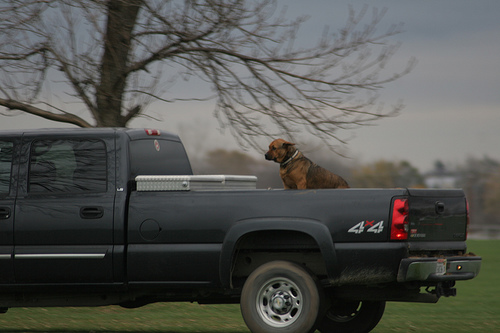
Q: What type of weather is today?
A: It is cloudy.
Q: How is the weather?
A: It is cloudy.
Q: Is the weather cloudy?
A: Yes, it is cloudy.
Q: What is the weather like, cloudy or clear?
A: It is cloudy.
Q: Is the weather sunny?
A: No, it is cloudy.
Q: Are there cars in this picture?
A: No, there are no cars.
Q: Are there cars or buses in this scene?
A: No, there are no cars or buses.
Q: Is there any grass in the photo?
A: Yes, there is grass.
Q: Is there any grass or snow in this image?
A: Yes, there is grass.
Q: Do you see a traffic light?
A: No, there are no traffic lights.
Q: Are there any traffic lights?
A: No, there are no traffic lights.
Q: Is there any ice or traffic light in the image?
A: No, there are no traffic lights or ice.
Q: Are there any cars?
A: No, there are no cars.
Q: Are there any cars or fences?
A: No, there are no cars or fences.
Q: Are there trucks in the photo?
A: Yes, there is a truck.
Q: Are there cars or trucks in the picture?
A: Yes, there is a truck.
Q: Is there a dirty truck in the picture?
A: Yes, there is a dirty truck.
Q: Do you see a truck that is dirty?
A: Yes, there is a truck that is dirty.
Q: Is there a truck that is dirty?
A: Yes, there is a truck that is dirty.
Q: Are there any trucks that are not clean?
A: Yes, there is a dirty truck.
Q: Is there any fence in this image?
A: No, there are no fences.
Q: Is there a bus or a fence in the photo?
A: No, there are no fences or buses.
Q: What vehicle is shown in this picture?
A: The vehicle is a truck.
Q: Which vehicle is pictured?
A: The vehicle is a truck.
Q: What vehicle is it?
A: The vehicle is a truck.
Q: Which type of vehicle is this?
A: That is a truck.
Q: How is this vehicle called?
A: That is a truck.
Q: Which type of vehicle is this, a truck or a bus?
A: That is a truck.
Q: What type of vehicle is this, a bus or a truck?
A: That is a truck.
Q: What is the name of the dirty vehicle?
A: The vehicle is a truck.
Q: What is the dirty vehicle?
A: The vehicle is a truck.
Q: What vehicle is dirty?
A: The vehicle is a truck.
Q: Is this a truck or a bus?
A: This is a truck.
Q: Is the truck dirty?
A: Yes, the truck is dirty.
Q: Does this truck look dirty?
A: Yes, the truck is dirty.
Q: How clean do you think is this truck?
A: The truck is dirty.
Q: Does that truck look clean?
A: No, the truck is dirty.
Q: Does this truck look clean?
A: No, the truck is dirty.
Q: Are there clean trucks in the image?
A: No, there is a truck but it is dirty.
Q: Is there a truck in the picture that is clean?
A: No, there is a truck but it is dirty.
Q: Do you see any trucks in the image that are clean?
A: No, there is a truck but it is dirty.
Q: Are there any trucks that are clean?
A: No, there is a truck but it is dirty.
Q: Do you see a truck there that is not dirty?
A: No, there is a truck but it is dirty.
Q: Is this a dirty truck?
A: Yes, this is a dirty truck.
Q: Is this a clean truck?
A: No, this is a dirty truck.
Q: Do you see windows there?
A: Yes, there are windows.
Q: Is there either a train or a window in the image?
A: Yes, there are windows.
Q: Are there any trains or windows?
A: Yes, there are windows.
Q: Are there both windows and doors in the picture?
A: Yes, there are both windows and a door.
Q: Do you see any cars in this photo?
A: No, there are no cars.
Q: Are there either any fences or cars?
A: No, there are no cars or fences.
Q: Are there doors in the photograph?
A: Yes, there is a door.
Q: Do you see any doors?
A: Yes, there is a door.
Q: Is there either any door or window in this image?
A: Yes, there is a door.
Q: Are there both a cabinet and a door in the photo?
A: No, there is a door but no cabinets.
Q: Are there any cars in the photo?
A: No, there are no cars.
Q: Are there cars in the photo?
A: No, there are no cars.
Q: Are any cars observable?
A: No, there are no cars.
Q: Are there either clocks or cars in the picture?
A: No, there are no cars or clocks.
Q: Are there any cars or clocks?
A: No, there are no cars or clocks.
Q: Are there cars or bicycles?
A: No, there are no cars or bicycles.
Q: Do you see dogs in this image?
A: Yes, there is a dog.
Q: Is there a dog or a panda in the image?
A: Yes, there is a dog.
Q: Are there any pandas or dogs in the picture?
A: Yes, there is a dog.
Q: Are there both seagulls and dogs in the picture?
A: No, there is a dog but no seagulls.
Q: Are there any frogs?
A: No, there are no frogs.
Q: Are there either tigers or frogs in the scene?
A: No, there are no frogs or tigers.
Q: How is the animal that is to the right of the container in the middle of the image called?
A: The animal is a dog.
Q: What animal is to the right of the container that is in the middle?
A: The animal is a dog.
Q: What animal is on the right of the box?
A: The animal is a dog.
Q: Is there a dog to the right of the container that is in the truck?
A: Yes, there is a dog to the right of the box.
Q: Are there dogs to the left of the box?
A: No, the dog is to the right of the box.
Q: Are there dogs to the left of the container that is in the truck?
A: No, the dog is to the right of the box.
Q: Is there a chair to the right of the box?
A: No, there is a dog to the right of the box.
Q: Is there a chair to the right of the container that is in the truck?
A: No, there is a dog to the right of the box.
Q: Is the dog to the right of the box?
A: Yes, the dog is to the right of the box.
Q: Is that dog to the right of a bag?
A: No, the dog is to the right of the box.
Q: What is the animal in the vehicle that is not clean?
A: The animal is a dog.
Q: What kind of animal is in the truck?
A: The animal is a dog.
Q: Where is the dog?
A: The dog is in the truck.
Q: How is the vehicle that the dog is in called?
A: The vehicle is a truck.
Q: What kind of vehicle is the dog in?
A: The dog is in the truck.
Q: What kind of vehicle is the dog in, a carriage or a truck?
A: The dog is in a truck.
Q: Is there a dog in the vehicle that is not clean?
A: Yes, there is a dog in the truck.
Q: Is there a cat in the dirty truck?
A: No, there is a dog in the truck.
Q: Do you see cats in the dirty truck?
A: No, there is a dog in the truck.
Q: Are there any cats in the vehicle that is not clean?
A: No, there is a dog in the truck.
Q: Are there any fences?
A: No, there are no fences.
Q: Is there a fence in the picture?
A: No, there are no fences.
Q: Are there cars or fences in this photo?
A: No, there are no fences or cars.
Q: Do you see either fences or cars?
A: No, there are no fences or cars.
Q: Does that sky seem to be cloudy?
A: Yes, the sky is cloudy.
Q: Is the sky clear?
A: No, the sky is cloudy.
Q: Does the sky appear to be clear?
A: No, the sky is cloudy.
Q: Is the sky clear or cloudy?
A: The sky is cloudy.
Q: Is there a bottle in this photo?
A: No, there are no bottles.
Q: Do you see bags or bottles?
A: No, there are no bottles or bags.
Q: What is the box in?
A: The box is in the truck.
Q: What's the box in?
A: The box is in the truck.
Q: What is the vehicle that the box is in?
A: The vehicle is a truck.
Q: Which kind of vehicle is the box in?
A: The box is in the truck.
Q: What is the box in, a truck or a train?
A: The box is in a truck.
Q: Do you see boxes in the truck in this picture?
A: Yes, there is a box in the truck.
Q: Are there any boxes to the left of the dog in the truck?
A: Yes, there is a box to the left of the dog.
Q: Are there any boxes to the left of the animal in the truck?
A: Yes, there is a box to the left of the dog.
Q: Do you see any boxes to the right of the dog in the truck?
A: No, the box is to the left of the dog.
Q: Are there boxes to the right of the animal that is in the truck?
A: No, the box is to the left of the dog.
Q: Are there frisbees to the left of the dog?
A: No, there is a box to the left of the dog.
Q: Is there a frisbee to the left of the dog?
A: No, there is a box to the left of the dog.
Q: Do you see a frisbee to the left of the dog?
A: No, there is a box to the left of the dog.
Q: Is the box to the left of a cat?
A: No, the box is to the left of the dog.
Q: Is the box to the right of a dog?
A: No, the box is to the left of a dog.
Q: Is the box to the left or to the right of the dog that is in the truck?
A: The box is to the left of the dog.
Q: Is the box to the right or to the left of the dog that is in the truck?
A: The box is to the left of the dog.